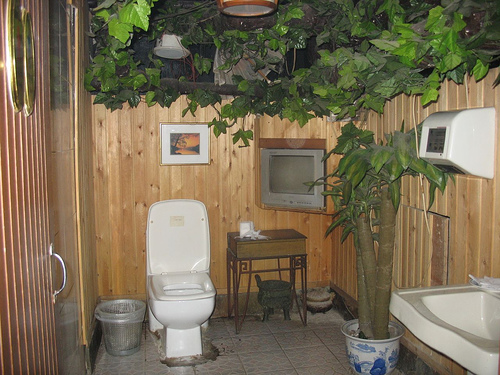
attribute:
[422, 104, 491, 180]
air hand dryer — white metal, white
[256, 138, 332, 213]
tv — gray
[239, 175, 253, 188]
wall — wooden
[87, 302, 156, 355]
trash receptacle — gray, silver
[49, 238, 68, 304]
pull handle — door, silver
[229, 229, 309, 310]
small table — brown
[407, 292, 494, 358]
sink — white, ceramic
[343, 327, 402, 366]
flower pot — blue& white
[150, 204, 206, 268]
toilet lid — white, plastic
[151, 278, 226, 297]
toilet seat — white, ceramic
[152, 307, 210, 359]
toilet bowl — white, ceramic